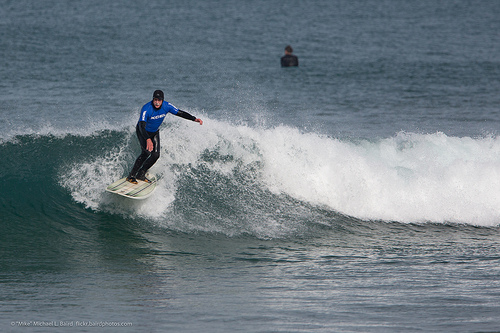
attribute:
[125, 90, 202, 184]
man — surfing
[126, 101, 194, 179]
wet suit — black, shiny, blue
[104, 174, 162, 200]
surfboard — white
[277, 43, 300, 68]
man — floating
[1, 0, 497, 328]
water — splashing, blue, here, ocean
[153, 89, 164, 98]
hat — black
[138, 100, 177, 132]
rash guard — blue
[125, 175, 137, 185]
bootie — black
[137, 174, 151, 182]
bootie — black